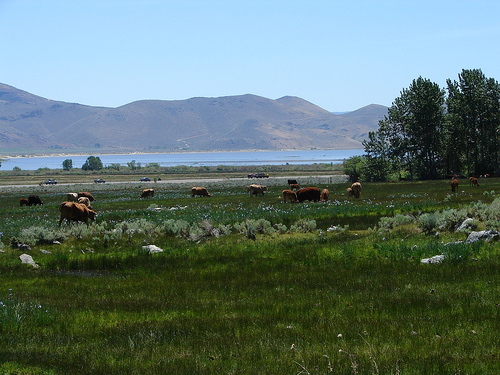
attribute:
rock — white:
[141, 238, 164, 256]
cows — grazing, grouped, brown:
[51, 179, 373, 226]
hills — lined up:
[2, 82, 365, 157]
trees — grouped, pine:
[366, 71, 499, 188]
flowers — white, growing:
[208, 202, 398, 213]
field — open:
[12, 197, 494, 370]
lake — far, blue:
[5, 154, 370, 165]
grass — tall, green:
[28, 270, 475, 360]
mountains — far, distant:
[6, 82, 389, 123]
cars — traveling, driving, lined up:
[38, 174, 165, 186]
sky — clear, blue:
[31, 16, 497, 68]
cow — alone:
[189, 185, 214, 202]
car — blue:
[91, 177, 110, 185]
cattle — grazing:
[6, 172, 485, 231]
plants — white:
[141, 202, 402, 217]